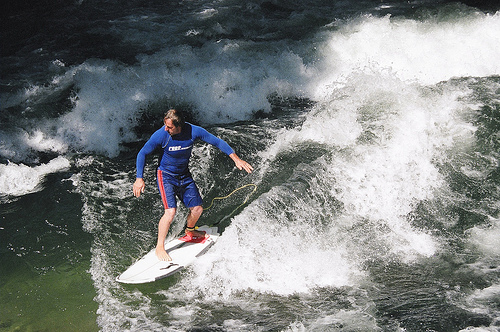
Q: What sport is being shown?
A: Surfing.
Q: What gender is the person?
A: Male.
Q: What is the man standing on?
A: Surfboard.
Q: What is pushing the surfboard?
A: Waves.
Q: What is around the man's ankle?
A: Safety cord.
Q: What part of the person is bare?
A: From the knees down.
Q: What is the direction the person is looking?
A: Left.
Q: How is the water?
A: Foamy.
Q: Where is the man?
A: On surfboard.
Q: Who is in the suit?
A: A man.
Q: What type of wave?
A: Vertical.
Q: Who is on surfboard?
A: A man.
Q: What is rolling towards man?
A: Wave.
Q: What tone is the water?
A: Murky.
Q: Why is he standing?
A: Balance.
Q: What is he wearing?
A: Wetsuit.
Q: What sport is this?
A: Surfing.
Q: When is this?
A: Daytime.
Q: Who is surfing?
A: Young man.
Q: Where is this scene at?
A: Ocean.